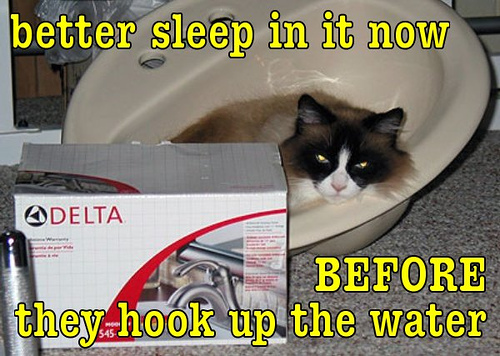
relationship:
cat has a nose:
[166, 91, 420, 215] [330, 170, 349, 195]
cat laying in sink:
[166, 91, 420, 215] [60, 1, 495, 255]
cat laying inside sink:
[166, 91, 420, 215] [60, 1, 495, 255]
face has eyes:
[298, 129, 387, 205] [312, 153, 370, 171]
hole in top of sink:
[212, 10, 236, 29] [60, 1, 495, 255]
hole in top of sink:
[136, 48, 167, 73] [60, 1, 495, 255]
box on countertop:
[15, 140, 292, 346] [5, 89, 499, 355]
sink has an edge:
[60, 1, 495, 255] [287, 94, 499, 257]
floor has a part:
[1, 94, 499, 354] [3, 97, 67, 232]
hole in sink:
[212, 10, 236, 29] [60, 1, 495, 255]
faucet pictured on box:
[164, 256, 245, 333] [15, 140, 292, 346]